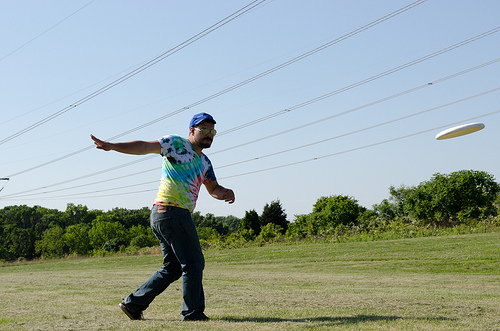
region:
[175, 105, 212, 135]
the cap is blue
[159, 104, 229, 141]
the cap is blue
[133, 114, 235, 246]
the shirt is colorful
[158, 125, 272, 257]
the shirt is colorful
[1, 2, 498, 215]
blue of daytime sky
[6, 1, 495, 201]
wires suspended in the air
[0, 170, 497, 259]
line of trees on horizon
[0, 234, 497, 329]
green grass on ground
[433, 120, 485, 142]
frisbee flying in the air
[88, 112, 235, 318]
man with extended arm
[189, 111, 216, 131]
blue hat on head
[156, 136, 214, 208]
short sleeved tee shirt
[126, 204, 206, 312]
blue jeans on legs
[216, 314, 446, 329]
shadow on green grass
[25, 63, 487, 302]
a man throws a frisbee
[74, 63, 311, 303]
the man wears jeans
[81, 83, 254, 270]
the hat is blue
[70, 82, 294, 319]
his shirt is tie dyed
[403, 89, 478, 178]
the frisbee is white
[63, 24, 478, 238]
there are wires in the sky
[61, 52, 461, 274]
power lines are black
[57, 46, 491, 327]
the season is summer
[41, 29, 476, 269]
playing with a frisbee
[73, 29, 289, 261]
his arms are stretched out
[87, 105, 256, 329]
This is a person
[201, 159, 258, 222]
Hand of a person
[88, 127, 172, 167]
Hand of a person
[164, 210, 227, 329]
Leg of a person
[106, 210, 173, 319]
Leg of a person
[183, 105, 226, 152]
Head of a person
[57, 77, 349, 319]
a man who just threw a frisbee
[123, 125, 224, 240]
a colorful tie dyed shirt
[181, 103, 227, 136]
a blue hat on head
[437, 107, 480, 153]
a white frisbee in air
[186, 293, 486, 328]
shadow of man on ground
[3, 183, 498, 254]
a row of trees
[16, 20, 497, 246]
wires above the man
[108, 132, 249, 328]
a t-shirt and jeans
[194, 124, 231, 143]
glass worn on face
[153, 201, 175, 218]
brand name tag on jeans